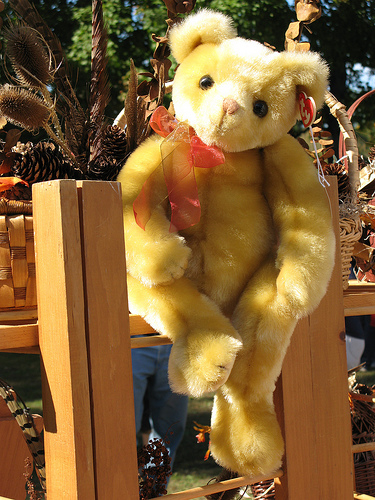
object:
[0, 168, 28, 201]
flowers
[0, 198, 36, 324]
basket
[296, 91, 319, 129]
tag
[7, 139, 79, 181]
pine cone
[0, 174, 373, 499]
fence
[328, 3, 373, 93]
trees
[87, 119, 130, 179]
pine cone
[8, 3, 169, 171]
bouquet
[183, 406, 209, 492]
ground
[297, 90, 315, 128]
ty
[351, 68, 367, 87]
sky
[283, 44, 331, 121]
ear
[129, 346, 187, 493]
jeans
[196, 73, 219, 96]
eye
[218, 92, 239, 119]
nose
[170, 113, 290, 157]
neck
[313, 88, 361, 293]
basket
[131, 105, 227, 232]
bow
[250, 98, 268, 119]
eyes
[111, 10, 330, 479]
bear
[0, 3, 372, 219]
background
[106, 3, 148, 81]
tree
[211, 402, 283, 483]
foot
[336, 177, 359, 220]
moss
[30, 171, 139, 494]
ladder